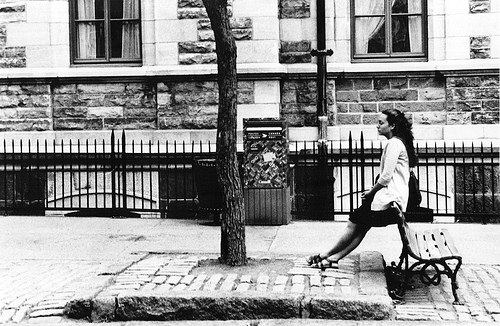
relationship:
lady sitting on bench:
[309, 94, 420, 274] [384, 192, 464, 298]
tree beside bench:
[174, 174, 272, 311] [391, 198, 462, 326]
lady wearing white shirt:
[305, 108, 420, 273] [379, 145, 419, 263]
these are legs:
[271, 205, 386, 309] [302, 218, 390, 326]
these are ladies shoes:
[244, 208, 375, 326] [274, 235, 335, 276]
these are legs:
[301, 195, 371, 294] [294, 212, 377, 324]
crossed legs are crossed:
[307, 194, 375, 270] [307, 188, 375, 293]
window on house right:
[342, 99, 401, 102] [327, 99, 365, 109]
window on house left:
[75, 51, 123, 89] [58, 99, 134, 181]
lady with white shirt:
[305, 108, 420, 273] [302, 97, 427, 227]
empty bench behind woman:
[382, 228, 467, 326] [274, 120, 398, 316]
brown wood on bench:
[424, 212, 468, 302] [401, 204, 459, 326]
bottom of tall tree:
[199, 206, 254, 290] [183, 116, 251, 326]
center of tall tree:
[200, 124, 272, 264] [193, 112, 252, 240]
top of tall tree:
[163, 50, 232, 127] [213, 184, 250, 256]